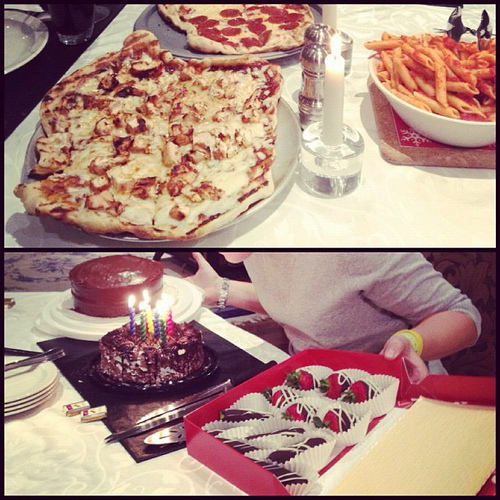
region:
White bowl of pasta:
[363, 25, 498, 150]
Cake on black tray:
[83, 324, 218, 393]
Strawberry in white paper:
[316, 401, 371, 443]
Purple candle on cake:
[122, 293, 139, 337]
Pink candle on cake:
[165, 299, 178, 336]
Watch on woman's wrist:
[207, 272, 232, 314]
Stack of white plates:
[0, 365, 61, 417]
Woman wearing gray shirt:
[188, 249, 487, 375]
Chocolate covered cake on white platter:
[33, 255, 205, 337]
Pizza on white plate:
[24, 29, 311, 242]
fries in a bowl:
[368, 30, 490, 120]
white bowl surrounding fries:
[402, 105, 467, 140]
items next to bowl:
[291, 25, 348, 100]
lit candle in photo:
[295, 41, 360, 121]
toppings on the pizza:
[187, 10, 268, 55]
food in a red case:
[225, 355, 390, 486]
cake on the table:
[105, 310, 215, 385]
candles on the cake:
[116, 286, 181, 332]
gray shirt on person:
[270, 255, 387, 315]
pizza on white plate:
[20, 42, 286, 228]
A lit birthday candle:
[128, 294, 135, 333]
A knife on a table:
[135, 359, 275, 421]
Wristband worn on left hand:
[394, 330, 423, 356]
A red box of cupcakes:
[183, 347, 498, 495]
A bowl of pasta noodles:
[365, 27, 496, 143]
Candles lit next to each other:
[122, 288, 174, 342]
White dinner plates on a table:
[1, 354, 56, 415]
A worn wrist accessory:
[217, 275, 227, 305]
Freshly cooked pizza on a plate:
[11, 28, 281, 238]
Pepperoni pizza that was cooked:
[157, 4, 312, 53]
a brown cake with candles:
[89, 276, 256, 426]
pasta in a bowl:
[376, 25, 476, 152]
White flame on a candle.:
[331, 29, 343, 56]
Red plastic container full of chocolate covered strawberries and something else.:
[181, 345, 499, 497]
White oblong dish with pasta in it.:
[366, 28, 499, 147]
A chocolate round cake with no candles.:
[65, 252, 165, 315]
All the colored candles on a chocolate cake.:
[126, 305, 173, 342]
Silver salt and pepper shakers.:
[298, 23, 333, 129]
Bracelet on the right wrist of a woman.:
[213, 276, 229, 311]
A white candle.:
[323, 52, 345, 149]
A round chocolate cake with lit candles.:
[94, 289, 205, 385]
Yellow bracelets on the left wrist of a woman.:
[391, 325, 423, 360]